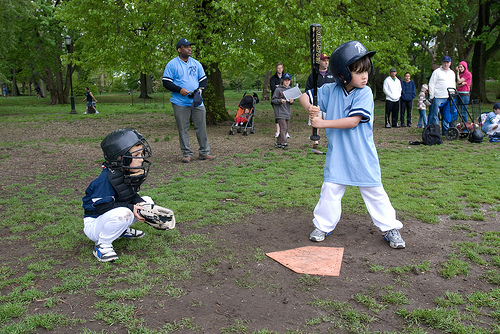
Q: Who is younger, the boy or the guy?
A: The boy is younger than the guy.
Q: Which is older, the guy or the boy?
A: The guy is older than the boy.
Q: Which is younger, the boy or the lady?
A: The boy is younger than the lady.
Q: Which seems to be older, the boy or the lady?
A: The lady is older than the boy.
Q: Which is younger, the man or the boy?
A: The boy is younger than the man.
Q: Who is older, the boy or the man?
A: The man is older than the boy.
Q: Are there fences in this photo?
A: No, there are no fences.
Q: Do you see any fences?
A: No, there are no fences.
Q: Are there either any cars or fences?
A: No, there are no fences or cars.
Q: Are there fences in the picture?
A: No, there are no fences.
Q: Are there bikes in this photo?
A: No, there are no bikes.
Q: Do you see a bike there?
A: No, there are no bikes.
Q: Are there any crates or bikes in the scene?
A: No, there are no bikes or crates.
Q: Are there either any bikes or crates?
A: No, there are no bikes or crates.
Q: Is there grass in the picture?
A: Yes, there is grass.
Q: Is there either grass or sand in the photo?
A: Yes, there is grass.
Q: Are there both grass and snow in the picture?
A: No, there is grass but no snow.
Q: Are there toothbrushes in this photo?
A: No, there are no toothbrushes.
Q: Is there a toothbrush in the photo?
A: No, there are no toothbrushes.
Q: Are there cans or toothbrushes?
A: No, there are no toothbrushes or cans.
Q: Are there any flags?
A: No, there are no flags.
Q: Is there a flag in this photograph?
A: No, there are no flags.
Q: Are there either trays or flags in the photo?
A: No, there are no flags or trays.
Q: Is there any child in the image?
A: Yes, there is a child.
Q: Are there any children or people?
A: Yes, there is a child.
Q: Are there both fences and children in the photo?
A: No, there is a child but no fences.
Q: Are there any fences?
A: No, there are no fences.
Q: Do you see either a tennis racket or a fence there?
A: No, there are no fences or rackets.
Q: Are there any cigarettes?
A: No, there are no cigarettes.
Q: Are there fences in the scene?
A: No, there are no fences.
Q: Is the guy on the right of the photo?
A: Yes, the guy is on the right of the image.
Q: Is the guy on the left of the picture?
A: No, the guy is on the right of the image.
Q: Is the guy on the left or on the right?
A: The guy is on the right of the image.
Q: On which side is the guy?
A: The guy is on the right of the image.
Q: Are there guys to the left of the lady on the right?
A: Yes, there is a guy to the left of the lady.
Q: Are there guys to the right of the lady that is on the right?
A: No, the guy is to the left of the lady.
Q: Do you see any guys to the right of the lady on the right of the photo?
A: No, the guy is to the left of the lady.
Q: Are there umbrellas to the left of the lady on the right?
A: No, there is a guy to the left of the lady.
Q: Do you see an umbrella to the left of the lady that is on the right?
A: No, there is a guy to the left of the lady.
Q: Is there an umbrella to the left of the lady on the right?
A: No, there is a guy to the left of the lady.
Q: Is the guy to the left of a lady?
A: Yes, the guy is to the left of a lady.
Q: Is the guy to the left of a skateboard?
A: No, the guy is to the left of a lady.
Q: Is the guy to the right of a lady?
A: No, the guy is to the left of a lady.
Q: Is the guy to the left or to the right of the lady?
A: The guy is to the left of the lady.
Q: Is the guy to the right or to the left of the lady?
A: The guy is to the left of the lady.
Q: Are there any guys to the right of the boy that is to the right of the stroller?
A: Yes, there is a guy to the right of the boy.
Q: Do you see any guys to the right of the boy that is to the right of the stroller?
A: Yes, there is a guy to the right of the boy.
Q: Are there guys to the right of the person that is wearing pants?
A: Yes, there is a guy to the right of the boy.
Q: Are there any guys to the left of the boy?
A: No, the guy is to the right of the boy.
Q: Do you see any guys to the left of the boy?
A: No, the guy is to the right of the boy.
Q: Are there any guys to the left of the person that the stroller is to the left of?
A: No, the guy is to the right of the boy.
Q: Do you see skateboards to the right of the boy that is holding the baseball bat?
A: No, there is a guy to the right of the boy.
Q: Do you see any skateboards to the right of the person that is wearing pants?
A: No, there is a guy to the right of the boy.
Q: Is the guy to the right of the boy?
A: Yes, the guy is to the right of the boy.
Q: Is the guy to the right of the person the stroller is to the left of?
A: Yes, the guy is to the right of the boy.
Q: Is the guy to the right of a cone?
A: No, the guy is to the right of the boy.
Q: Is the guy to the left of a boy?
A: No, the guy is to the right of a boy.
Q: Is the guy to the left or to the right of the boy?
A: The guy is to the right of the boy.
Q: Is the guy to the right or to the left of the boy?
A: The guy is to the right of the boy.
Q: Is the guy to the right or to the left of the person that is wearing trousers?
A: The guy is to the right of the boy.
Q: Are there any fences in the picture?
A: No, there are no fences.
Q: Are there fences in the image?
A: No, there are no fences.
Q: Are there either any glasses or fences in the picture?
A: No, there are no fences or glasses.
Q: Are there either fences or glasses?
A: No, there are no fences or glasses.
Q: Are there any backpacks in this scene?
A: Yes, there is a backpack.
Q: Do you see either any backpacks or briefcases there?
A: Yes, there is a backpack.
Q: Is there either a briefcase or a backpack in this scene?
A: Yes, there is a backpack.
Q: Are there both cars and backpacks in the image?
A: No, there is a backpack but no cars.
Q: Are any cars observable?
A: No, there are no cars.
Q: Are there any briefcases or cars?
A: No, there are no cars or briefcases.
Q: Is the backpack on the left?
A: No, the backpack is on the right of the image.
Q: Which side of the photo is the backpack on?
A: The backpack is on the right of the image.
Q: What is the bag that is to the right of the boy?
A: The bag is a backpack.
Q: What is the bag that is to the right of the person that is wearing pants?
A: The bag is a backpack.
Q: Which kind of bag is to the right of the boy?
A: The bag is a backpack.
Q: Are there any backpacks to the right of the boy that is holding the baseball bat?
A: Yes, there is a backpack to the right of the boy.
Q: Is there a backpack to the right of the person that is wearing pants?
A: Yes, there is a backpack to the right of the boy.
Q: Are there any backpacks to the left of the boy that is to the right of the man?
A: No, the backpack is to the right of the boy.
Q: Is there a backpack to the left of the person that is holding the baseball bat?
A: No, the backpack is to the right of the boy.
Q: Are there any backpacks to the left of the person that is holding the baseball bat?
A: No, the backpack is to the right of the boy.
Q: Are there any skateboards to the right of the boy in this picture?
A: No, there is a backpack to the right of the boy.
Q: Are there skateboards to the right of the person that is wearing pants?
A: No, there is a backpack to the right of the boy.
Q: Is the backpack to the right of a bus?
A: No, the backpack is to the right of the boy.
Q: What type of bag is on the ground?
A: The bag is a backpack.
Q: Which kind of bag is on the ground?
A: The bag is a backpack.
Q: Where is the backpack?
A: The backpack is on the ground.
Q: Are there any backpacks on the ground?
A: Yes, there is a backpack on the ground.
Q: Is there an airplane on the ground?
A: No, there is a backpack on the ground.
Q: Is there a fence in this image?
A: No, there are no fences.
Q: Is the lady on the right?
A: Yes, the lady is on the right of the image.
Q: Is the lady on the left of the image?
A: No, the lady is on the right of the image.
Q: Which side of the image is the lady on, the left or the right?
A: The lady is on the right of the image.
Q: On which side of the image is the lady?
A: The lady is on the right of the image.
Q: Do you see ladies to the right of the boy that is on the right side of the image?
A: Yes, there is a lady to the right of the boy.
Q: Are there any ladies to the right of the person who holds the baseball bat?
A: Yes, there is a lady to the right of the boy.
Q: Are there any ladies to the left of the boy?
A: No, the lady is to the right of the boy.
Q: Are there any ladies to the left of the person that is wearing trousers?
A: No, the lady is to the right of the boy.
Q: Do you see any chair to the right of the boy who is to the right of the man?
A: No, there is a lady to the right of the boy.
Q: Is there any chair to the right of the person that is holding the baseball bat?
A: No, there is a lady to the right of the boy.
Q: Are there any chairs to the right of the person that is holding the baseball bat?
A: No, there is a lady to the right of the boy.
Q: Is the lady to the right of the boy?
A: Yes, the lady is to the right of the boy.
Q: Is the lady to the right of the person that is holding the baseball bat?
A: Yes, the lady is to the right of the boy.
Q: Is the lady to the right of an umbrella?
A: No, the lady is to the right of the boy.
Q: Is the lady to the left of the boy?
A: No, the lady is to the right of the boy.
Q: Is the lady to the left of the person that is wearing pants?
A: No, the lady is to the right of the boy.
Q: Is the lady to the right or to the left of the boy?
A: The lady is to the right of the boy.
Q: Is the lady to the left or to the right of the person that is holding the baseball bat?
A: The lady is to the right of the boy.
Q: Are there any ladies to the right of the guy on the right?
A: Yes, there is a lady to the right of the guy.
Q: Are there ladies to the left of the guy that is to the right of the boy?
A: No, the lady is to the right of the guy.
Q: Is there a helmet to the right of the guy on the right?
A: No, there is a lady to the right of the guy.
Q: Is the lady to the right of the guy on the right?
A: Yes, the lady is to the right of the guy.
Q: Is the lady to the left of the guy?
A: No, the lady is to the right of the guy.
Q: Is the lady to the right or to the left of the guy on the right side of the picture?
A: The lady is to the right of the guy.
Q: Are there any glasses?
A: No, there are no glasses.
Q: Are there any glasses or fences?
A: No, there are no glasses or fences.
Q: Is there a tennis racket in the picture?
A: No, there are no rackets.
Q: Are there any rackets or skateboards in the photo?
A: No, there are no rackets or skateboards.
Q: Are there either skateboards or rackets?
A: No, there are no rackets or skateboards.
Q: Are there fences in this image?
A: No, there are no fences.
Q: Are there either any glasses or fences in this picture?
A: No, there are no fences or glasses.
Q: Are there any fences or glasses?
A: No, there are no fences or glasses.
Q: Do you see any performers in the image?
A: No, there are no performers.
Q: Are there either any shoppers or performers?
A: No, there are no performers or shoppers.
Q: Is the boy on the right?
A: Yes, the boy is on the right of the image.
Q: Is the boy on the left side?
A: No, the boy is on the right of the image.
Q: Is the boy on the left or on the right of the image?
A: The boy is on the right of the image.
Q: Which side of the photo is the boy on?
A: The boy is on the right of the image.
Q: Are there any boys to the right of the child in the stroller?
A: Yes, there is a boy to the right of the child.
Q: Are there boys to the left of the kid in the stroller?
A: No, the boy is to the right of the kid.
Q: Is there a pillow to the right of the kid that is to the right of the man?
A: No, there is a boy to the right of the kid.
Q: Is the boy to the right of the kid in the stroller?
A: Yes, the boy is to the right of the child.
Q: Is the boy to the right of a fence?
A: No, the boy is to the right of the child.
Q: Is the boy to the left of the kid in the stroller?
A: No, the boy is to the right of the kid.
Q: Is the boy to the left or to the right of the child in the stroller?
A: The boy is to the right of the child.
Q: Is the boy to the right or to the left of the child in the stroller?
A: The boy is to the right of the child.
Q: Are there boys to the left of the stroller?
A: No, the boy is to the right of the stroller.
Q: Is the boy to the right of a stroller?
A: Yes, the boy is to the right of a stroller.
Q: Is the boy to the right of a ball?
A: No, the boy is to the right of a stroller.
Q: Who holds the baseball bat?
A: The boy holds the baseball bat.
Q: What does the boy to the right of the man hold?
A: The boy holds the baseball bat.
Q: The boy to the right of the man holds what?
A: The boy holds the baseball bat.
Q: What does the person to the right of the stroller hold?
A: The boy holds the baseball bat.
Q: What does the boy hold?
A: The boy holds the baseball bat.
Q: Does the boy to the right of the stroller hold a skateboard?
A: No, the boy holds the baseball bat.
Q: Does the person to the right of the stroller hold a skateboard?
A: No, the boy holds the baseball bat.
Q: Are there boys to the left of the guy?
A: Yes, there is a boy to the left of the guy.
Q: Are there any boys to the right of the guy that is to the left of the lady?
A: No, the boy is to the left of the guy.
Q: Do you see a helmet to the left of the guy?
A: No, there is a boy to the left of the guy.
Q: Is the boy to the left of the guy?
A: Yes, the boy is to the left of the guy.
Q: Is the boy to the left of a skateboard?
A: No, the boy is to the left of the guy.